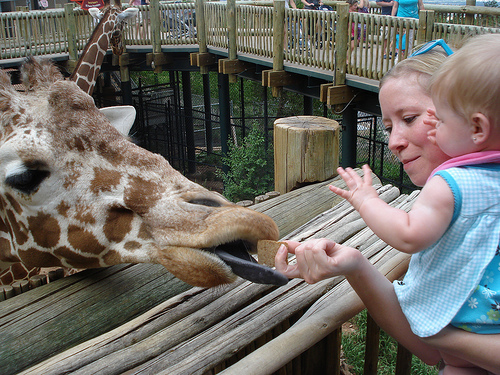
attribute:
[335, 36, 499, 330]
baby — blonde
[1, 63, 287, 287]
giraffe — feeding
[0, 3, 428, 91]
fence — wooden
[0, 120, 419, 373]
fence — wooden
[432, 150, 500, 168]
bib — pink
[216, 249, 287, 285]
tongue — black, long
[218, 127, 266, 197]
tree — small, green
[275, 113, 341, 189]
post — wooden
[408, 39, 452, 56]
sunglasses — blue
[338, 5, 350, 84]
post — wooden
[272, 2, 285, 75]
post — wooden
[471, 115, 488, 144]
ear — pierced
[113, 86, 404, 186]
fence — black, metal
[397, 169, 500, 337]
dress — blue, checkered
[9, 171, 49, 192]
eye — black